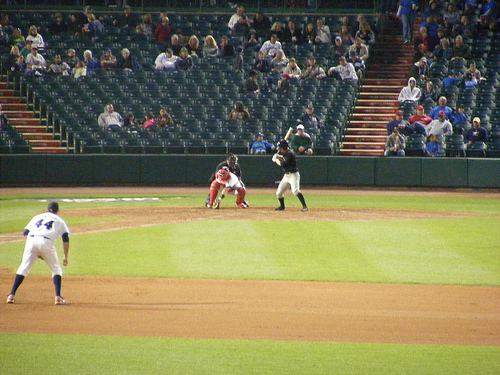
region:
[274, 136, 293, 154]
Man wearing protective helmet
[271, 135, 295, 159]
Man wearing black helmet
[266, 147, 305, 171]
Man wearing black shirt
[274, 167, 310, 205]
Man wearing black pants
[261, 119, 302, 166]
Man holding baseball bat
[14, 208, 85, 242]
Man wearing white shirt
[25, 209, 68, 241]
Shirt has number 44 on back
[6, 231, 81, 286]
Man wearing white pants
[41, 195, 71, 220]
Man wearing blue ball cap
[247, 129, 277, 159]
Spectator wearing blue shirt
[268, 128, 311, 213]
batter standing at home plate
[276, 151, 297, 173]
batter is wearing a black shirt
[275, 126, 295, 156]
batter is holding a wood bat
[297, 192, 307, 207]
batter wearing black socks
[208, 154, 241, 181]
umpire behind catcher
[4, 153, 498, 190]
low green wall behind batter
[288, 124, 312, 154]
person wearing white hat standing behind wall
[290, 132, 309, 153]
person wearing a green shirt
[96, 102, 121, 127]
person sitting in the stands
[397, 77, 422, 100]
person wearing white hoodie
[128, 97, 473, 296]
people playing baseball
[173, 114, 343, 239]
people on a baseball field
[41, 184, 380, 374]
a baseball field in stadium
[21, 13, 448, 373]
a baseball field stadium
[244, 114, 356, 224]
a baseball player batting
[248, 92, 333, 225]
a baseball playing holding a bat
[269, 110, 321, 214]
a baseball player wearing helmet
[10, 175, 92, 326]
a person in a baseball uniform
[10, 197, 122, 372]
a person wearing a blue hat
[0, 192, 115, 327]
a person leaning forward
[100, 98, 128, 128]
a male spectator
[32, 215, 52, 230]
the baseball player's number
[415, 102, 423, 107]
a red baseball cap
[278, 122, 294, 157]
a long baseball bat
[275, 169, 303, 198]
white baseball uniform pants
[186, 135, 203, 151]
a blue seat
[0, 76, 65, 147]
a row of red and white stairs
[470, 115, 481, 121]
a yellow baseball cap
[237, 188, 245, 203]
red safety gear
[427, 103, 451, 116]
a man's blue jacket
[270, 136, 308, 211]
Baseball player batting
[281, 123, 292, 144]
Brown bat held by baseball player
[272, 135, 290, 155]
Black helmet on baseball batter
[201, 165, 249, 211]
Catcher squatting in baseball game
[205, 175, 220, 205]
Red shinguard on baseball catcher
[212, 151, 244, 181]
Home plate umpire in baseball game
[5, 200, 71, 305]
Baseball infielder in game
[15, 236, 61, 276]
White pants on baseball infielder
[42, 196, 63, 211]
Blue hat on baseball infielder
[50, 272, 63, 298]
Blue sock on baseball infielder